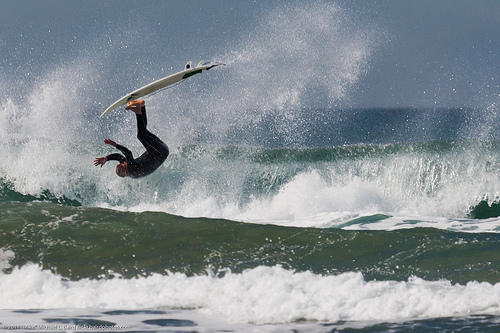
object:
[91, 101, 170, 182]
man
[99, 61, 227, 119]
surfboard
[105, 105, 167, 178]
wetsuit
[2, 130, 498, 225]
wave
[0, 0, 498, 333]
water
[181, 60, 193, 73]
fin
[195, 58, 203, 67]
fin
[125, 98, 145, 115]
foot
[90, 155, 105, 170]
hand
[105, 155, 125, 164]
arm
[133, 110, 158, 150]
leg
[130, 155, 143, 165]
chest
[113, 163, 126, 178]
head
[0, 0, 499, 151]
water droplets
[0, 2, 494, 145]
air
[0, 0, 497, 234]
foam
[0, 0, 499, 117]
sky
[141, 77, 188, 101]
cord